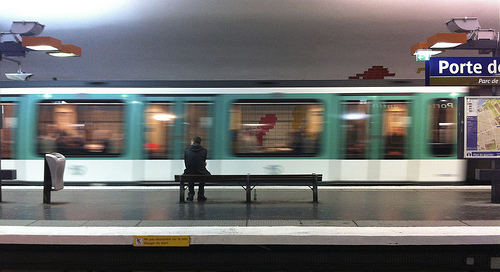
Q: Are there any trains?
A: Yes, there is a train.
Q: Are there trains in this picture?
A: Yes, there is a train.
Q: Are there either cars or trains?
A: Yes, there is a train.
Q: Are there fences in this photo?
A: No, there are no fences.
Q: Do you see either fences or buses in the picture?
A: No, there are no fences or buses.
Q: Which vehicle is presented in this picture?
A: The vehicle is a train.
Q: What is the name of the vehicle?
A: The vehicle is a train.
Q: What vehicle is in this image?
A: The vehicle is a train.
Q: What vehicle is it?
A: The vehicle is a train.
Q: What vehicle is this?
A: This is a train.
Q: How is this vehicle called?
A: This is a train.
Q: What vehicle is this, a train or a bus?
A: This is a train.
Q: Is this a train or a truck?
A: This is a train.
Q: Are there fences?
A: No, there are no fences.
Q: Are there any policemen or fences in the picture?
A: No, there are no fences or policemen.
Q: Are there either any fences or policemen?
A: No, there are no fences or policemen.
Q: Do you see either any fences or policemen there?
A: No, there are no fences or policemen.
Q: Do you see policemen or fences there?
A: No, there are no fences or policemen.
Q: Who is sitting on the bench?
A: The man is sitting on the bench.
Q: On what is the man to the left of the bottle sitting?
A: The man is sitting on the bench.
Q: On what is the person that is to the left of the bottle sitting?
A: The man is sitting on the bench.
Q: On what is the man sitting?
A: The man is sitting on the bench.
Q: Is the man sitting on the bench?
A: Yes, the man is sitting on the bench.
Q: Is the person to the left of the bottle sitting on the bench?
A: Yes, the man is sitting on the bench.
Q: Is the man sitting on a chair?
A: No, the man is sitting on the bench.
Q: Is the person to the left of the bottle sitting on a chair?
A: No, the man is sitting on the bench.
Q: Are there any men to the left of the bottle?
A: Yes, there is a man to the left of the bottle.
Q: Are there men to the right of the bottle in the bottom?
A: No, the man is to the left of the bottle.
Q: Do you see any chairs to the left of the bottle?
A: No, there is a man to the left of the bottle.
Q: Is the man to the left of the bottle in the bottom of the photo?
A: Yes, the man is to the left of the bottle.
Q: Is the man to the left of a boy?
A: No, the man is to the left of the bottle.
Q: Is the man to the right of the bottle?
A: No, the man is to the left of the bottle.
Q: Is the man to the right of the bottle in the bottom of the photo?
A: No, the man is to the left of the bottle.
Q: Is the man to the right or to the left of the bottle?
A: The man is to the left of the bottle.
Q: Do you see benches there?
A: Yes, there is a bench.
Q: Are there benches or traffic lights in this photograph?
A: Yes, there is a bench.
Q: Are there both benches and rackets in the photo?
A: No, there is a bench but no rackets.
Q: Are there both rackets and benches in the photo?
A: No, there is a bench but no rackets.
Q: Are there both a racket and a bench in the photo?
A: No, there is a bench but no rackets.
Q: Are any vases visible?
A: No, there are no vases.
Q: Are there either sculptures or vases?
A: No, there are no vases or sculptures.